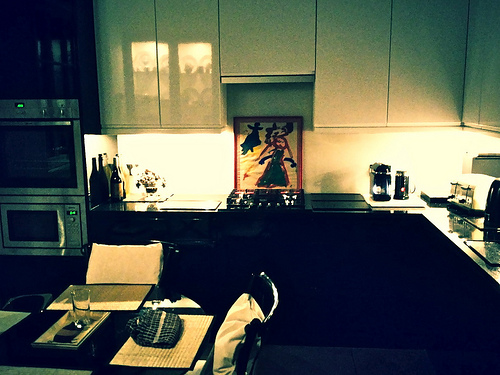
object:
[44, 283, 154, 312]
placemat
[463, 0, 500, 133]
cabinets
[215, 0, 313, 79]
cabinets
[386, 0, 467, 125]
cabinets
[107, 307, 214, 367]
tablecloth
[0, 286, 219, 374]
dinner table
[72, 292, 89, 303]
glass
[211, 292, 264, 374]
pillow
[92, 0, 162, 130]
cabinet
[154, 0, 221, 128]
cabinet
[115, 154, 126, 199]
bottles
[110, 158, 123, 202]
bottle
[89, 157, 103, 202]
bottle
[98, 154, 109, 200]
bottle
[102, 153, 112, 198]
bottle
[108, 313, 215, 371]
place mat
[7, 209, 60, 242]
microwave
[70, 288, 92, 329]
cup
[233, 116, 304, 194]
photo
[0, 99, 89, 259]
appliances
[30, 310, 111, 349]
bowl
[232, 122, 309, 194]
toaster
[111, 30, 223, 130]
reflection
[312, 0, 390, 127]
cabinet doors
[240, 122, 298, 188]
art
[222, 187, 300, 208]
stove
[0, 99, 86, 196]
oven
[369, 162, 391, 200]
coffe pot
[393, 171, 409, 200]
coffe pot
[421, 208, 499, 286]
counter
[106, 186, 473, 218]
counter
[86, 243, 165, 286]
cushion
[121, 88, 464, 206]
wall